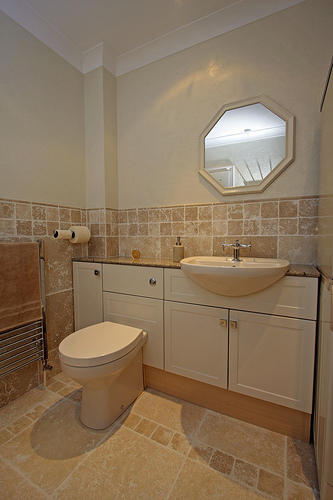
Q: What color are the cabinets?
A: White.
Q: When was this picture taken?
A: Today.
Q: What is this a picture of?
A: Bathroom.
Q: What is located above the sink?
A: Mirror.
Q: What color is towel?
A: Brown.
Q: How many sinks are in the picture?
A: One.